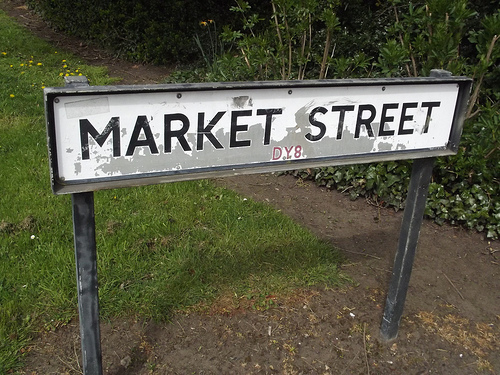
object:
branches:
[461, 35, 500, 120]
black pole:
[376, 158, 439, 336]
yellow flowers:
[35, 60, 47, 68]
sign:
[41, 76, 476, 195]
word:
[77, 107, 284, 160]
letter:
[77, 115, 122, 160]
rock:
[117, 353, 131, 373]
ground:
[0, 0, 500, 374]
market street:
[78, 100, 442, 161]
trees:
[25, 0, 499, 195]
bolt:
[174, 91, 182, 99]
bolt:
[285, 87, 293, 96]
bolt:
[378, 86, 388, 93]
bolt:
[52, 97, 62, 106]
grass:
[0, 5, 350, 375]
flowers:
[6, 92, 16, 99]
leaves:
[435, 181, 476, 208]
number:
[294, 143, 303, 158]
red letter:
[271, 145, 285, 160]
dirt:
[0, 172, 499, 374]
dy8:
[271, 145, 303, 163]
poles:
[70, 189, 107, 373]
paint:
[53, 83, 463, 182]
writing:
[304, 99, 441, 143]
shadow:
[124, 225, 403, 374]